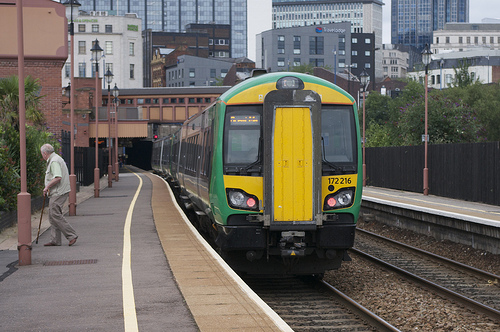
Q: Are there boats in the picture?
A: No, there are no boats.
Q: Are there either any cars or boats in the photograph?
A: No, there are no boats or cars.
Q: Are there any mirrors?
A: No, there are no mirrors.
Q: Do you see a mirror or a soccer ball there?
A: No, there are no mirrors or soccer balls.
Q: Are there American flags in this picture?
A: No, there are no American flags.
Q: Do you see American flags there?
A: No, there are no American flags.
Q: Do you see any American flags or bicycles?
A: No, there are no American flags or bicycles.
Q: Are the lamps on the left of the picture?
A: Yes, the lamps are on the left of the image.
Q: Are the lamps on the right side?
A: No, the lamps are on the left of the image.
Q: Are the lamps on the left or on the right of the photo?
A: The lamps are on the left of the image.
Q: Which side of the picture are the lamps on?
A: The lamps are on the left of the image.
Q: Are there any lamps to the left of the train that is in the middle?
A: Yes, there are lamps to the left of the train.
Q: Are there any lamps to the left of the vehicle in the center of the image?
A: Yes, there are lamps to the left of the train.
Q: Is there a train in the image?
A: Yes, there is a train.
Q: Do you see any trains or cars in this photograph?
A: Yes, there is a train.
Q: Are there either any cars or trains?
A: Yes, there is a train.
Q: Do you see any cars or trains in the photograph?
A: Yes, there is a train.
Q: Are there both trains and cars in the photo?
A: No, there is a train but no cars.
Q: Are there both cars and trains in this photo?
A: No, there is a train but no cars.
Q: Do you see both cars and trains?
A: No, there is a train but no cars.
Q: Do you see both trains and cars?
A: No, there is a train but no cars.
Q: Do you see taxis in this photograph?
A: No, there are no taxis.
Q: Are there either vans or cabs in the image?
A: No, there are no cabs or vans.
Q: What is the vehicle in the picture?
A: The vehicle is a train.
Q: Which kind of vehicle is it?
A: The vehicle is a train.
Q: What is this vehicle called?
A: This is a train.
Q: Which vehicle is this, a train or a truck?
A: This is a train.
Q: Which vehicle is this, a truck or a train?
A: This is a train.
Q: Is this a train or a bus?
A: This is a train.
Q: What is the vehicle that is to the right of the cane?
A: The vehicle is a train.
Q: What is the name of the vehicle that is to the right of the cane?
A: The vehicle is a train.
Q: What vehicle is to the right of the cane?
A: The vehicle is a train.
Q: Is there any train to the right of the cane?
A: Yes, there is a train to the right of the cane.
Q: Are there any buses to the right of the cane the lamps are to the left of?
A: No, there is a train to the right of the cane.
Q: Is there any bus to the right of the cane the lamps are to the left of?
A: No, there is a train to the right of the cane.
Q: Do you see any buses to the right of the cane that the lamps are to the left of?
A: No, there is a train to the right of the cane.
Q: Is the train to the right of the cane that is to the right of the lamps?
A: Yes, the train is to the right of the cane.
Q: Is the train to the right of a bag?
A: No, the train is to the right of the cane.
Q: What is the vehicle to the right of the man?
A: The vehicle is a train.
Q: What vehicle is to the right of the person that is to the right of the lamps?
A: The vehicle is a train.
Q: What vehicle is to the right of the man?
A: The vehicle is a train.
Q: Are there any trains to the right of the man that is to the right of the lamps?
A: Yes, there is a train to the right of the man.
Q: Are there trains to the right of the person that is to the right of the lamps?
A: Yes, there is a train to the right of the man.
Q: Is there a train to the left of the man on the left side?
A: No, the train is to the right of the man.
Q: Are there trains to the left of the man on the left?
A: No, the train is to the right of the man.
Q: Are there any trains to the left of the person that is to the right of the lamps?
A: No, the train is to the right of the man.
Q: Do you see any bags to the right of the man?
A: No, there is a train to the right of the man.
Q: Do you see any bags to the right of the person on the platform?
A: No, there is a train to the right of the man.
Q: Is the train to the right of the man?
A: Yes, the train is to the right of the man.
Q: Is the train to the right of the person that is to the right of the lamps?
A: Yes, the train is to the right of the man.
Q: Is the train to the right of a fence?
A: No, the train is to the right of the man.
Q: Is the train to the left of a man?
A: No, the train is to the right of a man.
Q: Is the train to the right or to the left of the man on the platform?
A: The train is to the right of the man.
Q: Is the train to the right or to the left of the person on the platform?
A: The train is to the right of the man.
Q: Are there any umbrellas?
A: No, there are no umbrellas.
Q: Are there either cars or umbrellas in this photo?
A: No, there are no umbrellas or cars.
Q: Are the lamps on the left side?
A: Yes, the lamps are on the left of the image.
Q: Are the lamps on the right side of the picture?
A: No, the lamps are on the left of the image.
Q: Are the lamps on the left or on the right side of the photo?
A: The lamps are on the left of the image.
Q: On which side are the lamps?
A: The lamps are on the left of the image.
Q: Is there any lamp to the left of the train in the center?
A: Yes, there are lamps to the left of the train.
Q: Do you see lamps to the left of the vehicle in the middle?
A: Yes, there are lamps to the left of the train.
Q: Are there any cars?
A: No, there are no cars.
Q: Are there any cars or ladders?
A: No, there are no cars or ladders.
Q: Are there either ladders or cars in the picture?
A: No, there are no cars or ladders.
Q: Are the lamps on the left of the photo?
A: Yes, the lamps are on the left of the image.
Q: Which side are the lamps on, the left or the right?
A: The lamps are on the left of the image.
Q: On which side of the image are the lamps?
A: The lamps are on the left of the image.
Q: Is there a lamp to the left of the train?
A: Yes, there are lamps to the left of the train.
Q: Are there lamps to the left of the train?
A: Yes, there are lamps to the left of the train.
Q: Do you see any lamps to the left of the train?
A: Yes, there are lamps to the left of the train.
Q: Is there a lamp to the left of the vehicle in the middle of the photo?
A: Yes, there are lamps to the left of the train.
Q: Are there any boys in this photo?
A: No, there are no boys.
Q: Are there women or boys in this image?
A: No, there are no boys or women.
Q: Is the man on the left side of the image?
A: Yes, the man is on the left of the image.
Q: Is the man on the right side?
A: No, the man is on the left of the image.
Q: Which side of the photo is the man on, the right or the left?
A: The man is on the left of the image.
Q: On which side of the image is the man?
A: The man is on the left of the image.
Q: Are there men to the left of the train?
A: Yes, there is a man to the left of the train.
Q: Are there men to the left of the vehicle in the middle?
A: Yes, there is a man to the left of the train.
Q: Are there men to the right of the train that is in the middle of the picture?
A: No, the man is to the left of the train.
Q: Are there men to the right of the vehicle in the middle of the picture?
A: No, the man is to the left of the train.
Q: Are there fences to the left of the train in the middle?
A: No, there is a man to the left of the train.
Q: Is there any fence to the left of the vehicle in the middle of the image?
A: No, there is a man to the left of the train.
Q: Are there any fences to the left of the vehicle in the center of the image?
A: No, there is a man to the left of the train.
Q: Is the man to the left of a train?
A: Yes, the man is to the left of a train.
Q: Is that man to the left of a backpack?
A: No, the man is to the left of a train.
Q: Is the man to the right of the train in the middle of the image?
A: No, the man is to the left of the train.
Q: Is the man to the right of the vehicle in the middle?
A: No, the man is to the left of the train.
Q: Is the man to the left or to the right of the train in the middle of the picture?
A: The man is to the left of the train.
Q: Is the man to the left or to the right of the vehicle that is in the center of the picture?
A: The man is to the left of the train.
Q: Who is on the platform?
A: The man is on the platform.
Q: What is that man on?
A: The man is on the platform.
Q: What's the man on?
A: The man is on the platform.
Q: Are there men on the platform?
A: Yes, there is a man on the platform.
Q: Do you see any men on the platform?
A: Yes, there is a man on the platform.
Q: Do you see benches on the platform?
A: No, there is a man on the platform.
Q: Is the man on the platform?
A: Yes, the man is on the platform.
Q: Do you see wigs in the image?
A: No, there are no wigs.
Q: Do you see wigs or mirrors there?
A: No, there are no wigs or mirrors.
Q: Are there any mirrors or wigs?
A: No, there are no wigs or mirrors.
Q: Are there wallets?
A: No, there are no wallets.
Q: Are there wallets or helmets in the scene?
A: No, there are no wallets or helmets.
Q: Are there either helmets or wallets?
A: No, there are no wallets or helmets.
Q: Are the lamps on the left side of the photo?
A: Yes, the lamps are on the left of the image.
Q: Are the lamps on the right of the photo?
A: No, the lamps are on the left of the image.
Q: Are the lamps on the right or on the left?
A: The lamps are on the left of the image.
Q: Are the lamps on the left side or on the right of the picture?
A: The lamps are on the left of the image.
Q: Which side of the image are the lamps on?
A: The lamps are on the left of the image.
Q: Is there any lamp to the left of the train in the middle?
A: Yes, there are lamps to the left of the train.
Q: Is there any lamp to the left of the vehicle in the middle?
A: Yes, there are lamps to the left of the train.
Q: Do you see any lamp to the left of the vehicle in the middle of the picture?
A: Yes, there are lamps to the left of the train.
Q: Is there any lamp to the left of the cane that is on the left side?
A: Yes, there are lamps to the left of the cane.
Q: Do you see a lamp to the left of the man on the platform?
A: Yes, there are lamps to the left of the man.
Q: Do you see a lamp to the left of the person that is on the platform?
A: Yes, there are lamps to the left of the man.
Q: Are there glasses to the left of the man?
A: No, there are lamps to the left of the man.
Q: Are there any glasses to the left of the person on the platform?
A: No, there are lamps to the left of the man.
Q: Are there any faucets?
A: No, there are no faucets.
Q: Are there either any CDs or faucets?
A: No, there are no faucets or cds.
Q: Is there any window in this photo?
A: Yes, there is a window.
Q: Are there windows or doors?
A: Yes, there is a window.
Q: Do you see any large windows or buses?
A: Yes, there is a large window.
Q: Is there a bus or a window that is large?
A: Yes, the window is large.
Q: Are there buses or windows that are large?
A: Yes, the window is large.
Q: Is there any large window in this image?
A: Yes, there is a large window.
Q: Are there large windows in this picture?
A: Yes, there is a large window.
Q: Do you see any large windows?
A: Yes, there is a large window.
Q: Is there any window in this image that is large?
A: Yes, there is a large window.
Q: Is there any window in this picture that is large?
A: Yes, there is a window that is large.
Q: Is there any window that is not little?
A: Yes, there is a large window.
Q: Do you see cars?
A: No, there are no cars.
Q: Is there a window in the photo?
A: Yes, there is a window.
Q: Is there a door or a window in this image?
A: Yes, there is a window.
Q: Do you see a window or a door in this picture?
A: Yes, there is a window.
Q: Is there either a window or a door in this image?
A: Yes, there is a window.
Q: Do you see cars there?
A: No, there are no cars.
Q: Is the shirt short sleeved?
A: Yes, the shirt is short sleeved.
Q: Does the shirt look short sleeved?
A: Yes, the shirt is short sleeved.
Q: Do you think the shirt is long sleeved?
A: No, the shirt is short sleeved.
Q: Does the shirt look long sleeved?
A: No, the shirt is short sleeved.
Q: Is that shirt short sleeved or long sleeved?
A: The shirt is short sleeved.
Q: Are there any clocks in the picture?
A: No, there are no clocks.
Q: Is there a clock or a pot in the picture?
A: No, there are no clocks or pots.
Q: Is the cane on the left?
A: Yes, the cane is on the left of the image.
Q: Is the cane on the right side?
A: No, the cane is on the left of the image.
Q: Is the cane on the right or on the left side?
A: The cane is on the left of the image.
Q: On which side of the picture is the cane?
A: The cane is on the left of the image.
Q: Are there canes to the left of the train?
A: Yes, there is a cane to the left of the train.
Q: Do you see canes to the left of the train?
A: Yes, there is a cane to the left of the train.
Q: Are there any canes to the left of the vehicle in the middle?
A: Yes, there is a cane to the left of the train.